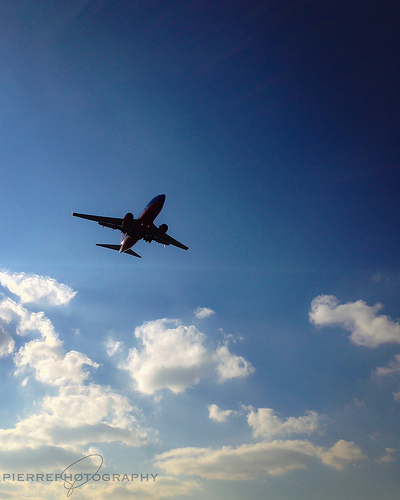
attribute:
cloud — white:
[308, 294, 397, 350]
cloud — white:
[107, 319, 252, 394]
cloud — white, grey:
[1, 270, 143, 478]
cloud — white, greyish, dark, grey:
[5, 437, 365, 499]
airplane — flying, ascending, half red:
[73, 194, 190, 257]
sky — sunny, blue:
[3, 3, 397, 492]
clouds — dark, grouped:
[0, 269, 399, 499]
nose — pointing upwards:
[139, 193, 165, 225]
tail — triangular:
[96, 236, 141, 259]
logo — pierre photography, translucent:
[3, 458, 159, 495]